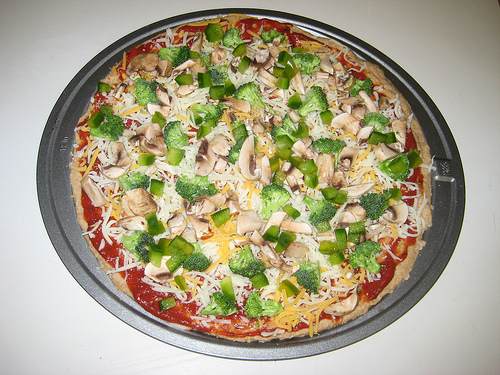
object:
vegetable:
[295, 261, 322, 293]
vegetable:
[96, 80, 106, 95]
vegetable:
[144, 179, 170, 196]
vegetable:
[284, 206, 295, 218]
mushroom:
[255, 122, 266, 129]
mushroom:
[381, 200, 409, 226]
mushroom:
[155, 137, 167, 158]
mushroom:
[80, 175, 108, 206]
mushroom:
[118, 219, 149, 232]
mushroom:
[385, 119, 412, 147]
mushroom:
[196, 196, 214, 215]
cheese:
[230, 182, 258, 201]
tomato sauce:
[380, 221, 410, 285]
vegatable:
[181, 253, 210, 274]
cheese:
[392, 218, 412, 253]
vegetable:
[161, 117, 192, 154]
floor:
[239, 117, 369, 166]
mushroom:
[353, 104, 366, 120]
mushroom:
[254, 64, 277, 86]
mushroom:
[151, 59, 173, 77]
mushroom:
[215, 158, 227, 173]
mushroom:
[279, 262, 294, 275]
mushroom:
[253, 231, 268, 241]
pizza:
[67, 15, 439, 341]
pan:
[40, 5, 468, 366]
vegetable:
[202, 21, 224, 44]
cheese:
[402, 179, 427, 223]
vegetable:
[219, 182, 232, 204]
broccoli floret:
[226, 243, 265, 276]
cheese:
[78, 146, 98, 181]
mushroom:
[236, 134, 263, 179]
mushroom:
[281, 221, 309, 234]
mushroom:
[123, 185, 158, 216]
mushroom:
[343, 120, 359, 135]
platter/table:
[0, 0, 500, 375]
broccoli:
[159, 44, 190, 66]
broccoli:
[89, 114, 125, 142]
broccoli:
[228, 247, 262, 277]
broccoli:
[358, 189, 392, 217]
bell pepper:
[273, 135, 294, 148]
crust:
[400, 110, 441, 225]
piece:
[275, 321, 290, 328]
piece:
[278, 319, 299, 321]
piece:
[300, 297, 329, 313]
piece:
[306, 312, 313, 339]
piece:
[206, 211, 219, 237]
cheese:
[207, 215, 219, 237]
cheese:
[301, 298, 326, 313]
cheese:
[306, 310, 313, 337]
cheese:
[268, 323, 291, 328]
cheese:
[277, 284, 297, 300]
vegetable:
[162, 143, 183, 165]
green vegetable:
[380, 150, 422, 180]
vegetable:
[348, 240, 385, 276]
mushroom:
[256, 155, 274, 184]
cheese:
[233, 28, 252, 45]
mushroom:
[98, 161, 126, 180]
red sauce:
[131, 34, 186, 46]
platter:
[29, 19, 469, 350]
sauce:
[354, 256, 392, 296]